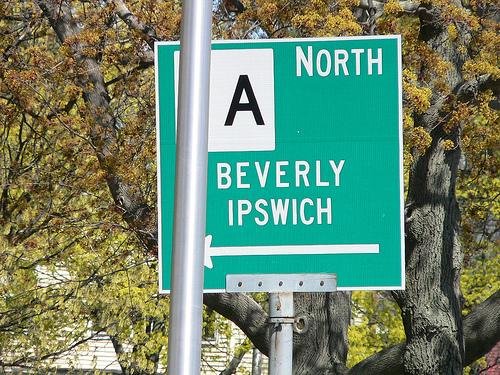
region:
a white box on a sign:
[152, 35, 292, 178]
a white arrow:
[165, 220, 387, 289]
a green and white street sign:
[122, 20, 424, 343]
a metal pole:
[149, 2, 237, 369]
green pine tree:
[12, 112, 134, 343]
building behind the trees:
[9, 246, 168, 373]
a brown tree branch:
[394, 178, 476, 360]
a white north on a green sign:
[288, 26, 420, 96]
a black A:
[205, 28, 275, 157]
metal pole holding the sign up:
[250, 290, 304, 373]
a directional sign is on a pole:
[145, 33, 413, 373]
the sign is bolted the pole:
[222, 268, 337, 340]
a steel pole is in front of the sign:
[150, 0, 210, 370]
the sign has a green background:
[150, 31, 405, 291]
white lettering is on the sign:
[213, 156, 346, 228]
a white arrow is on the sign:
[200, 228, 381, 270]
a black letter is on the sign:
[216, 65, 266, 127]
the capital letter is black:
[220, 71, 267, 126]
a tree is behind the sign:
[12, 1, 493, 371]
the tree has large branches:
[229, 67, 496, 370]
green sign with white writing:
[144, 20, 436, 326]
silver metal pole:
[134, 2, 229, 374]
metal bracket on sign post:
[262, 311, 309, 338]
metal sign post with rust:
[219, 265, 343, 374]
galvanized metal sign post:
[217, 266, 350, 373]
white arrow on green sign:
[184, 228, 389, 286]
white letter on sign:
[289, 39, 319, 83]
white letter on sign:
[314, 43, 333, 82]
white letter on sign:
[330, 46, 352, 81]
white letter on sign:
[347, 43, 369, 78]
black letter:
[214, 64, 296, 146]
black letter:
[212, 54, 263, 179]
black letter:
[235, 37, 291, 167]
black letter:
[223, 33, 320, 188]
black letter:
[187, 27, 267, 139]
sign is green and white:
[156, 68, 379, 290]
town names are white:
[203, 149, 339, 282]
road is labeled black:
[200, 54, 274, 145]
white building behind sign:
[5, 226, 232, 353]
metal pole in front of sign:
[178, 23, 202, 360]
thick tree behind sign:
[281, 6, 456, 363]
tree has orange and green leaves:
[5, 88, 131, 299]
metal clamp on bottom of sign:
[198, 267, 324, 322]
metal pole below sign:
[260, 298, 302, 365]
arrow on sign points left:
[199, 223, 394, 276]